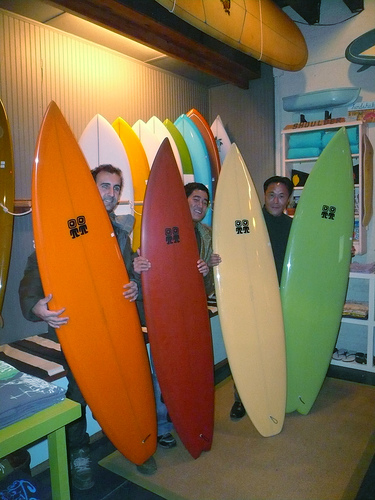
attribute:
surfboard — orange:
[31, 99, 158, 465]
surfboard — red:
[139, 134, 216, 459]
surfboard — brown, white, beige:
[209, 141, 287, 438]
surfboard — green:
[280, 125, 356, 416]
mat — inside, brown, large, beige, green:
[95, 375, 374, 498]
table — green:
[0, 397, 85, 500]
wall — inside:
[0, 10, 209, 343]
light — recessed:
[40, 8, 165, 96]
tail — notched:
[190, 435, 215, 461]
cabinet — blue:
[26, 312, 227, 465]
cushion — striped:
[0, 295, 218, 381]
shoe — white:
[343, 350, 356, 362]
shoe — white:
[332, 349, 346, 362]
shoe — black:
[355, 352, 367, 365]